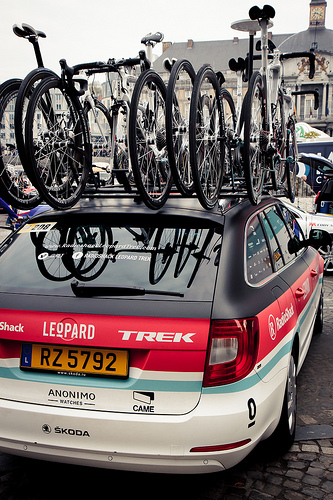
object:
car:
[0, 188, 326, 481]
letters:
[33, 237, 164, 270]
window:
[0, 223, 225, 308]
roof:
[151, 25, 332, 71]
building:
[145, 3, 332, 146]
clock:
[308, 1, 328, 30]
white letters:
[0, 312, 199, 351]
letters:
[267, 300, 295, 340]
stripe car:
[166, 374, 263, 398]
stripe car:
[252, 334, 310, 350]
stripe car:
[11, 365, 198, 405]